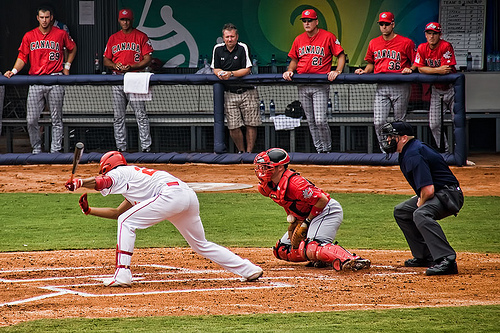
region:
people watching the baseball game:
[14, 21, 469, 141]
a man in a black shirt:
[211, 24, 271, 143]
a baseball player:
[61, 139, 274, 297]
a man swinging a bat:
[64, 140, 263, 275]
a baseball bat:
[66, 137, 89, 178]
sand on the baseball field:
[19, 235, 461, 295]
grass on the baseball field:
[6, 193, 486, 248]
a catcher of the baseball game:
[250, 138, 370, 278]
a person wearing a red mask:
[251, 150, 354, 261]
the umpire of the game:
[376, 117, 466, 257]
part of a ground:
[270, 263, 309, 316]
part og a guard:
[334, 245, 349, 255]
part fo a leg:
[208, 230, 248, 287]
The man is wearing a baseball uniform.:
[2, 7, 84, 163]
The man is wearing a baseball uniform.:
[98, 7, 165, 152]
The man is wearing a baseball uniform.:
[279, 8, 356, 157]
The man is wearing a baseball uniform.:
[357, 10, 417, 153]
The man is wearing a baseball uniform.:
[412, 19, 472, 159]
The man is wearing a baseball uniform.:
[44, 139, 266, 299]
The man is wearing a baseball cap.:
[98, 7, 165, 158]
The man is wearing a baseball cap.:
[276, 7, 355, 155]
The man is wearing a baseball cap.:
[353, 8, 415, 152]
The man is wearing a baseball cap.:
[411, 15, 469, 161]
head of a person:
[91, 138, 134, 175]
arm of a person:
[82, 178, 123, 196]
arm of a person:
[96, 196, 156, 226]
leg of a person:
[99, 212, 171, 267]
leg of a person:
[162, 213, 266, 273]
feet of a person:
[90, 274, 147, 295]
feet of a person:
[235, 265, 279, 303]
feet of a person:
[318, 250, 388, 287]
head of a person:
[245, 141, 308, 202]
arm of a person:
[288, 180, 330, 238]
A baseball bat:
[70, 141, 85, 187]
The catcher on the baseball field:
[249, 148, 366, 272]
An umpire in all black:
[377, 121, 468, 273]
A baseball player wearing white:
[67, 143, 260, 286]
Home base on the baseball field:
[4, 246, 383, 313]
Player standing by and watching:
[17, 5, 457, 155]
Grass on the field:
[1, 191, 498, 251]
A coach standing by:
[211, 23, 262, 149]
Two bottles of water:
[258, 98, 274, 116]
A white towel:
[122, 70, 157, 100]